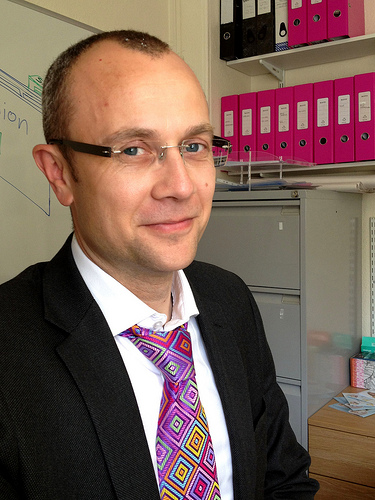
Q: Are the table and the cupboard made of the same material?
A: No, the table is made of wood and the cupboard is made of metal.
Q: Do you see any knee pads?
A: No, there are no knee pads.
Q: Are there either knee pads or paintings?
A: No, there are no knee pads or paintings.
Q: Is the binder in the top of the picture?
A: Yes, the binder is in the top of the image.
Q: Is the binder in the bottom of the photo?
A: No, the binder is in the top of the image.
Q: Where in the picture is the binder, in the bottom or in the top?
A: The binder is in the top of the image.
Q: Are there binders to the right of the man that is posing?
A: Yes, there is a binder to the right of the man.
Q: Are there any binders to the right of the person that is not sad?
A: Yes, there is a binder to the right of the man.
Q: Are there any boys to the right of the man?
A: No, there is a binder to the right of the man.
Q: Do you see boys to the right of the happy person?
A: No, there is a binder to the right of the man.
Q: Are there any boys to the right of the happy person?
A: No, there is a binder to the right of the man.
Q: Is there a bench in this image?
A: No, there are no benches.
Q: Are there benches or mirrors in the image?
A: No, there are no benches or mirrors.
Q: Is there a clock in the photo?
A: No, there are no clocks.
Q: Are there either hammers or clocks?
A: No, there are no clocks or hammers.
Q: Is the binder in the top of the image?
A: Yes, the binder is in the top of the image.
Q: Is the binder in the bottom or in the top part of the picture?
A: The binder is in the top of the image.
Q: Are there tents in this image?
A: No, there are no tents.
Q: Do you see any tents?
A: No, there are no tents.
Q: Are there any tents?
A: No, there are no tents.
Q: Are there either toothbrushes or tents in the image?
A: No, there are no tents or toothbrushes.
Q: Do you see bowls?
A: No, there are no bowls.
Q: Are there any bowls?
A: No, there are no bowls.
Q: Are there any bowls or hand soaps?
A: No, there are no bowls or hand soaps.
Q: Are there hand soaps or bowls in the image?
A: No, there are no bowls or hand soaps.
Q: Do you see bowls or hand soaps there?
A: No, there are no bowls or hand soaps.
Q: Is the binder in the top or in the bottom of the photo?
A: The binder is in the top of the image.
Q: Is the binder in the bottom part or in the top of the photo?
A: The binder is in the top of the image.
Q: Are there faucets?
A: No, there are no faucets.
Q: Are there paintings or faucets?
A: No, there are no faucets or paintings.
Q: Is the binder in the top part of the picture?
A: Yes, the binder is in the top of the image.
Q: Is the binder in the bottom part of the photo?
A: No, the binder is in the top of the image.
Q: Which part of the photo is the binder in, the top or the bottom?
A: The binder is in the top of the image.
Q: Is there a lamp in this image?
A: No, there are no lamps.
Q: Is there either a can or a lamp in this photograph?
A: No, there are no lamps or cans.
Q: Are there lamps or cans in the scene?
A: No, there are no lamps or cans.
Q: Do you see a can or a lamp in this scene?
A: No, there are no lamps or cans.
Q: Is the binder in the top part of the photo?
A: Yes, the binder is in the top of the image.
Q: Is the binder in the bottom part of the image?
A: No, the binder is in the top of the image.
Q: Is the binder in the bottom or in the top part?
A: The binder is in the top of the image.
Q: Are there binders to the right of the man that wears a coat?
A: Yes, there is a binder to the right of the man.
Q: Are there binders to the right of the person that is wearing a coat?
A: Yes, there is a binder to the right of the man.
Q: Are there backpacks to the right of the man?
A: No, there is a binder to the right of the man.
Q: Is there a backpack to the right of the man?
A: No, there is a binder to the right of the man.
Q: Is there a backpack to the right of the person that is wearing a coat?
A: No, there is a binder to the right of the man.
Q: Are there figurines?
A: No, there are no figurines.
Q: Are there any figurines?
A: No, there are no figurines.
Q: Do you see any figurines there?
A: No, there are no figurines.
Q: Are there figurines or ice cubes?
A: No, there are no figurines or ice cubes.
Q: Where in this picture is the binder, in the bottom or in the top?
A: The binder is in the top of the image.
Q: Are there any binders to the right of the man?
A: Yes, there is a binder to the right of the man.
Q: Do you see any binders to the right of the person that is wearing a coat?
A: Yes, there is a binder to the right of the man.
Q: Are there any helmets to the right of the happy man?
A: No, there is a binder to the right of the man.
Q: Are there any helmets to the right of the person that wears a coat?
A: No, there is a binder to the right of the man.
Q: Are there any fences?
A: No, there are no fences.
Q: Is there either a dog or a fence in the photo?
A: No, there are no fences or dogs.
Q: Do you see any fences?
A: No, there are no fences.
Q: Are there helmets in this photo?
A: No, there are no helmets.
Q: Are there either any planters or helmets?
A: No, there are no helmets or planters.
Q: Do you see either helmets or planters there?
A: No, there are no helmets or planters.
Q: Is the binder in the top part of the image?
A: Yes, the binder is in the top of the image.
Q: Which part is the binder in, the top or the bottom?
A: The binder is in the top of the image.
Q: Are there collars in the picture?
A: Yes, there is a collar.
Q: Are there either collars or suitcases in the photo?
A: Yes, there is a collar.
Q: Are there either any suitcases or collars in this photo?
A: Yes, there is a collar.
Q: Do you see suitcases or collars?
A: Yes, there is a collar.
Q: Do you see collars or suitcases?
A: Yes, there is a collar.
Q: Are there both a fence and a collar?
A: No, there is a collar but no fences.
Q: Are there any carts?
A: No, there are no carts.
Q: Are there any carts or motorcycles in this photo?
A: No, there are no carts or motorcycles.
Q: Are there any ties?
A: Yes, there is a tie.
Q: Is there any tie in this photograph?
A: Yes, there is a tie.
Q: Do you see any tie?
A: Yes, there is a tie.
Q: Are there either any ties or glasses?
A: Yes, there is a tie.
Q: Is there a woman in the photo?
A: No, there are no women.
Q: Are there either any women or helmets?
A: No, there are no women or helmets.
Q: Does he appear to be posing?
A: Yes, the man is posing.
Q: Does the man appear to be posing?
A: Yes, the man is posing.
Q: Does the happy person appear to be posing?
A: Yes, the man is posing.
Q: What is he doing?
A: The man is posing.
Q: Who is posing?
A: The man is posing.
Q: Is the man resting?
A: No, the man is posing.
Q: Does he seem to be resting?
A: No, the man is posing.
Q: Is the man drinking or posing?
A: The man is posing.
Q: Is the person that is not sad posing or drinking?
A: The man is posing.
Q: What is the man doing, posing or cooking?
A: The man is posing.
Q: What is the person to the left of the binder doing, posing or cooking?
A: The man is posing.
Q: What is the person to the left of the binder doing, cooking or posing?
A: The man is posing.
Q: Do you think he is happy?
A: Yes, the man is happy.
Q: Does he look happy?
A: Yes, the man is happy.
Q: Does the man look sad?
A: No, the man is happy.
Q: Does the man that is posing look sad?
A: No, the man is happy.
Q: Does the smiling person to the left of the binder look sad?
A: No, the man is happy.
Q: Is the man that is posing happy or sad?
A: The man is happy.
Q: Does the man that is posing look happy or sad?
A: The man is happy.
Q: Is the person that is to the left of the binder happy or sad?
A: The man is happy.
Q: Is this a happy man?
A: Yes, this is a happy man.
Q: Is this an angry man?
A: No, this is a happy man.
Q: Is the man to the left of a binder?
A: Yes, the man is to the left of a binder.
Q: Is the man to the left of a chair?
A: No, the man is to the left of a binder.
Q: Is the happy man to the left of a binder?
A: Yes, the man is to the left of a binder.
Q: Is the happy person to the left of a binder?
A: Yes, the man is to the left of a binder.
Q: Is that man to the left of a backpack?
A: No, the man is to the left of a binder.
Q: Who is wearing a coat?
A: The man is wearing a coat.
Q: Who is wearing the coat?
A: The man is wearing a coat.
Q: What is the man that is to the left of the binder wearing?
A: The man is wearing a coat.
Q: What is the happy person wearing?
A: The man is wearing a coat.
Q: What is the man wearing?
A: The man is wearing a coat.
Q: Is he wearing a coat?
A: Yes, the man is wearing a coat.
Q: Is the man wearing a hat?
A: No, the man is wearing a coat.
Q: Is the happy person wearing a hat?
A: No, the man is wearing a coat.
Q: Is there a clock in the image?
A: No, there are no clocks.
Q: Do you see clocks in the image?
A: No, there are no clocks.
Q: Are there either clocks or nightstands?
A: No, there are no clocks or nightstands.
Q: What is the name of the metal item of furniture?
A: The piece of furniture is a cupboard.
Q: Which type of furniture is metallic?
A: The furniture is a cupboard.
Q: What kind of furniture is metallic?
A: The furniture is a cupboard.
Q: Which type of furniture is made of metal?
A: The furniture is a cupboard.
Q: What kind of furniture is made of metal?
A: The furniture is a cupboard.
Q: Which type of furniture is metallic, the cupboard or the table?
A: The cupboard is metallic.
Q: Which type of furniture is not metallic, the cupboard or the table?
A: The table is not metallic.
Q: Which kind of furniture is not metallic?
A: The furniture is a table.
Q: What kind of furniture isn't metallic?
A: The furniture is a table.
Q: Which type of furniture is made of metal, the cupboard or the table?
A: The cupboard is made of metal.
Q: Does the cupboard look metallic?
A: Yes, the cupboard is metallic.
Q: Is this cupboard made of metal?
A: Yes, the cupboard is made of metal.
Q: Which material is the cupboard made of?
A: The cupboard is made of metal.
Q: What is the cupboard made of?
A: The cupboard is made of metal.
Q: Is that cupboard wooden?
A: No, the cupboard is metallic.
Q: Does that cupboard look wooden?
A: No, the cupboard is metallic.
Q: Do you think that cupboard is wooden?
A: No, the cupboard is metallic.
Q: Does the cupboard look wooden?
A: No, the cupboard is metallic.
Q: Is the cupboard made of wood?
A: No, the cupboard is made of metal.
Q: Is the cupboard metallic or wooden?
A: The cupboard is metallic.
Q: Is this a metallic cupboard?
A: Yes, this is a metallic cupboard.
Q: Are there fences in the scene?
A: No, there are no fences.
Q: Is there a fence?
A: No, there are no fences.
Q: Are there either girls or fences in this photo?
A: No, there are no fences or girls.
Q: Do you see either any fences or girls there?
A: No, there are no fences or girls.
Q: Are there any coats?
A: Yes, there is a coat.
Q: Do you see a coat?
A: Yes, there is a coat.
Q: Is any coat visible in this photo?
A: Yes, there is a coat.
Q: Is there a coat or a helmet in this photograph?
A: Yes, there is a coat.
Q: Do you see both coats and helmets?
A: No, there is a coat but no helmets.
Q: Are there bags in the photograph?
A: No, there are no bags.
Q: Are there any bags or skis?
A: No, there are no bags or skis.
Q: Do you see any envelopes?
A: No, there are no envelopes.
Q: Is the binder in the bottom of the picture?
A: No, the binder is in the top of the image.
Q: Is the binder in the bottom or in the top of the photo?
A: The binder is in the top of the image.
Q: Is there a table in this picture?
A: Yes, there is a table.